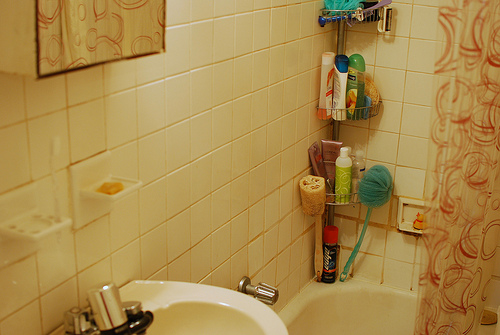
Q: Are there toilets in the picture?
A: No, there are no toilets.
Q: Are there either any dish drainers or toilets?
A: No, there are no toilets or dish drainers.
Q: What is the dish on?
A: The dish is on the wall.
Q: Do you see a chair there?
A: No, there are no chairs.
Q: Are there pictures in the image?
A: No, there are no pictures.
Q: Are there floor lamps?
A: No, there are no floor lamps.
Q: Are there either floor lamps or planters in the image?
A: No, there are no floor lamps or planters.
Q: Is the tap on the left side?
A: Yes, the tap is on the left of the image.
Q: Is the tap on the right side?
A: No, the tap is on the left of the image.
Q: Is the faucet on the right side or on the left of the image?
A: The faucet is on the left of the image.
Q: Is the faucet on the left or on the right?
A: The faucet is on the left of the image.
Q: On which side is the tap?
A: The tap is on the left of the image.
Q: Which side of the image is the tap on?
A: The tap is on the left of the image.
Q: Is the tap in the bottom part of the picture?
A: Yes, the tap is in the bottom of the image.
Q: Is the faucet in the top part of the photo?
A: No, the faucet is in the bottom of the image.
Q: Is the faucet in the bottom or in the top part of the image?
A: The faucet is in the bottom of the image.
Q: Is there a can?
A: Yes, there is a can.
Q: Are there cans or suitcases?
A: Yes, there is a can.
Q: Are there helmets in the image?
A: No, there are no helmets.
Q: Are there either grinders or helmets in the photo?
A: No, there are no helmets or grinders.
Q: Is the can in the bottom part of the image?
A: Yes, the can is in the bottom of the image.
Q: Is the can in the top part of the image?
A: No, the can is in the bottom of the image.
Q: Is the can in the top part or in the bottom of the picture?
A: The can is in the bottom of the image.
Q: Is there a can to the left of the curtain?
A: Yes, there is a can to the left of the curtain.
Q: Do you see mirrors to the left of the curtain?
A: No, there is a can to the left of the curtain.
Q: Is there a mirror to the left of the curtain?
A: No, there is a can to the left of the curtain.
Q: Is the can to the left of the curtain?
A: Yes, the can is to the left of the curtain.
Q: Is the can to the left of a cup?
A: No, the can is to the left of the curtain.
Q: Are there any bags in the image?
A: No, there are no bags.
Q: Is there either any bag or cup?
A: No, there are no bags or cups.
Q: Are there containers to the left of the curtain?
A: Yes, there is a container to the left of the curtain.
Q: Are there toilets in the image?
A: No, there are no toilets.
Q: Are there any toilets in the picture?
A: No, there are no toilets.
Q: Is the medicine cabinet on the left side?
A: Yes, the medicine cabinet is on the left of the image.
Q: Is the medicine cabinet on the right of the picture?
A: No, the medicine cabinet is on the left of the image.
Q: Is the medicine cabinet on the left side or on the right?
A: The medicine cabinet is on the left of the image.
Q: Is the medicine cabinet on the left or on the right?
A: The medicine cabinet is on the left of the image.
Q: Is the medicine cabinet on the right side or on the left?
A: The medicine cabinet is on the left of the image.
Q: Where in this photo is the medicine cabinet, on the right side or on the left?
A: The medicine cabinet is on the left of the image.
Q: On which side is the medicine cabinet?
A: The medicine cabinet is on the left of the image.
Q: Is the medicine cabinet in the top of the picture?
A: Yes, the medicine cabinet is in the top of the image.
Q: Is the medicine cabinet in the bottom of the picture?
A: No, the medicine cabinet is in the top of the image.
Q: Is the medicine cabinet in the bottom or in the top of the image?
A: The medicine cabinet is in the top of the image.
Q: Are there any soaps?
A: Yes, there is a soap.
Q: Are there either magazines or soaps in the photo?
A: Yes, there is a soap.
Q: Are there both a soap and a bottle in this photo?
A: Yes, there are both a soap and a bottle.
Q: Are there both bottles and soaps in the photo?
A: Yes, there are both a soap and a bottle.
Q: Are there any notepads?
A: No, there are no notepads.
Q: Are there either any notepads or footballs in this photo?
A: No, there are no notepads or footballs.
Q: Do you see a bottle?
A: Yes, there is a bottle.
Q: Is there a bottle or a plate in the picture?
A: Yes, there is a bottle.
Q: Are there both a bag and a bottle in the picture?
A: No, there is a bottle but no bags.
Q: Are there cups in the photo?
A: No, there are no cups.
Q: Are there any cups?
A: No, there are no cups.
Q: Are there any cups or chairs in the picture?
A: No, there are no cups or chairs.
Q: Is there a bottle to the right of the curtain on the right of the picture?
A: No, the bottle is to the left of the curtain.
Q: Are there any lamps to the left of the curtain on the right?
A: No, there is a bottle to the left of the curtain.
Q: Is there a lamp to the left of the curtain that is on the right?
A: No, there is a bottle to the left of the curtain.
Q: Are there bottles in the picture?
A: Yes, there is a bottle.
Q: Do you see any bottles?
A: Yes, there is a bottle.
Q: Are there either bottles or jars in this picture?
A: Yes, there is a bottle.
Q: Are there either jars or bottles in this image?
A: Yes, there is a bottle.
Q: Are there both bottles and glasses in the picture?
A: No, there is a bottle but no glasses.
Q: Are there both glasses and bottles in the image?
A: No, there is a bottle but no glasses.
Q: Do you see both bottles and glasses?
A: No, there is a bottle but no glasses.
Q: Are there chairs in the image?
A: No, there are no chairs.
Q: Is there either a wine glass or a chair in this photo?
A: No, there are no chairs or wine glasses.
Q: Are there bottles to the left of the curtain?
A: Yes, there is a bottle to the left of the curtain.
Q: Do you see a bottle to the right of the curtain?
A: No, the bottle is to the left of the curtain.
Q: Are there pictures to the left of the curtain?
A: No, there is a bottle to the left of the curtain.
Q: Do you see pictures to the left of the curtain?
A: No, there is a bottle to the left of the curtain.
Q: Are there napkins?
A: No, there are no napkins.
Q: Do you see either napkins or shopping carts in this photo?
A: No, there are no napkins or shopping carts.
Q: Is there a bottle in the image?
A: Yes, there is a bottle.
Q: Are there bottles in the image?
A: Yes, there is a bottle.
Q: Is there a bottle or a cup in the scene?
A: Yes, there is a bottle.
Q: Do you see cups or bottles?
A: Yes, there is a bottle.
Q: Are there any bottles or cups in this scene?
A: Yes, there is a bottle.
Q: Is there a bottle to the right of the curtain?
A: No, the bottle is to the left of the curtain.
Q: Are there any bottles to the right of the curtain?
A: No, the bottle is to the left of the curtain.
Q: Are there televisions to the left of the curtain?
A: No, there is a bottle to the left of the curtain.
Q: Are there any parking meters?
A: No, there are no parking meters.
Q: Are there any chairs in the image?
A: No, there are no chairs.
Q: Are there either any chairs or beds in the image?
A: No, there are no chairs or beds.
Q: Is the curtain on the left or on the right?
A: The curtain is on the right of the image.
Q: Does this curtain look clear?
A: Yes, the curtain is clear.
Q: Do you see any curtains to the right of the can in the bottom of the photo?
A: Yes, there is a curtain to the right of the can.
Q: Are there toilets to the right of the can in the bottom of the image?
A: No, there is a curtain to the right of the can.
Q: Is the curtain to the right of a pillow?
A: No, the curtain is to the right of the can.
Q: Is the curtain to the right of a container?
A: Yes, the curtain is to the right of a container.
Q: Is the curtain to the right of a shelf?
A: No, the curtain is to the right of a container.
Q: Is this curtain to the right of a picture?
A: No, the curtain is to the right of the bottle.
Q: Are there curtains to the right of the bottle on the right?
A: Yes, there is a curtain to the right of the bottle.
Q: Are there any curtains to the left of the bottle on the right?
A: No, the curtain is to the right of the bottle.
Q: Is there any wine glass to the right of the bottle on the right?
A: No, there is a curtain to the right of the bottle.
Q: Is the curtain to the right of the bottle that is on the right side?
A: Yes, the curtain is to the right of the bottle.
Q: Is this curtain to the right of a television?
A: No, the curtain is to the right of the bottle.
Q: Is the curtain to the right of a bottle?
A: Yes, the curtain is to the right of a bottle.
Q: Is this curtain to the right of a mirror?
A: No, the curtain is to the right of a bottle.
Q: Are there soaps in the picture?
A: Yes, there is a soap.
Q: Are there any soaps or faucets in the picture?
A: Yes, there is a soap.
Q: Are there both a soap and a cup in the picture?
A: No, there is a soap but no cups.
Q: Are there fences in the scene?
A: No, there are no fences.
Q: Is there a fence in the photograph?
A: No, there are no fences.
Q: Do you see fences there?
A: No, there are no fences.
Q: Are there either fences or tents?
A: No, there are no fences or tents.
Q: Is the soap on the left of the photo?
A: Yes, the soap is on the left of the image.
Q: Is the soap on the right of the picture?
A: No, the soap is on the left of the image.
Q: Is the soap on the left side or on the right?
A: The soap is on the left of the image.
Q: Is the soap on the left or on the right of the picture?
A: The soap is on the left of the image.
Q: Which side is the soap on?
A: The soap is on the left of the image.